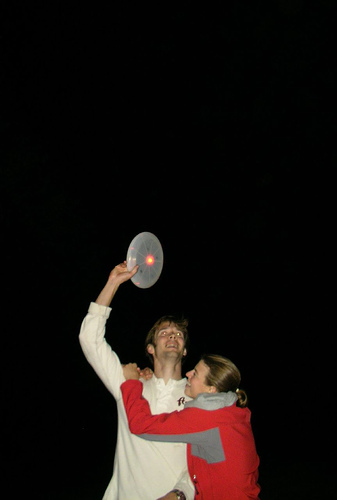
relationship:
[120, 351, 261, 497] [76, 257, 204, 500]
woman huge man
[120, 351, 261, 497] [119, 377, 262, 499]
woman has clothing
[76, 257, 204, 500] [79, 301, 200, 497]
man has shirt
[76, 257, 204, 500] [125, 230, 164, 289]
man has disc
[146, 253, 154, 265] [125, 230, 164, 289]
light in disc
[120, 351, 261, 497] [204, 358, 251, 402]
woman has hair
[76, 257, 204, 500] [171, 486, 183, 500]
man wears watch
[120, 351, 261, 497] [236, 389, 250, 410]
woman wears ponytail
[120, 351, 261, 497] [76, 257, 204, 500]
woman with man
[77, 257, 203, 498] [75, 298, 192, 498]
man with shirt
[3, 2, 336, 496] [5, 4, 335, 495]
photo taken night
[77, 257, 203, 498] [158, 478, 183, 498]
man wearing watch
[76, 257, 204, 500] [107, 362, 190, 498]
man in shirt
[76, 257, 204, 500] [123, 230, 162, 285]
man holding disc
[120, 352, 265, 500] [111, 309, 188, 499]
woman hugging man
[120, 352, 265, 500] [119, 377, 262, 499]
woman wearing clothing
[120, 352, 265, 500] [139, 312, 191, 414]
woman hugging man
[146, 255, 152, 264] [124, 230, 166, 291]
light on frisbee